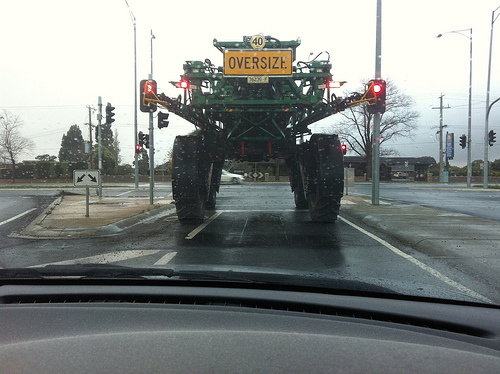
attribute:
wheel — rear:
[171, 129, 228, 206]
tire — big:
[299, 126, 351, 228]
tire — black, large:
[307, 134, 342, 224]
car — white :
[151, 56, 401, 241]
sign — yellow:
[222, 46, 294, 78]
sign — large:
[217, 49, 295, 84]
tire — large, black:
[291, 135, 359, 240]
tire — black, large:
[176, 147, 217, 211]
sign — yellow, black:
[223, 48, 293, 76]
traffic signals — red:
[366, 77, 391, 114]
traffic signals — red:
[139, 77, 157, 111]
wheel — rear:
[299, 149, 346, 227]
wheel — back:
[297, 151, 345, 219]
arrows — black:
[64, 170, 109, 197]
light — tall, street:
[439, 10, 484, 205]